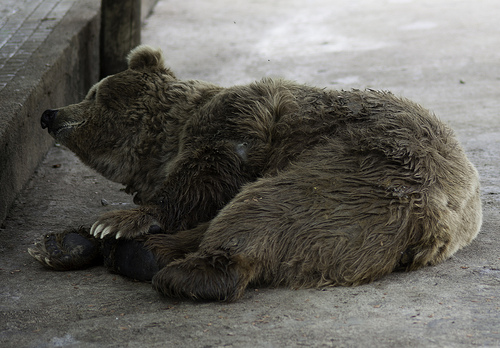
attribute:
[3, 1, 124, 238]
floor — raised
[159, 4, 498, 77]
ground — clean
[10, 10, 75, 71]
floor — bricked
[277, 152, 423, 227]
fur — brown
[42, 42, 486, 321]
fur — brown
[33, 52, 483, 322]
bear — on bear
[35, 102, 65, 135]
nose — black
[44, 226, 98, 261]
paw — black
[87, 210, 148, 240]
paw — white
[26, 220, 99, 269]
paw — white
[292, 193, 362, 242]
fur — rugged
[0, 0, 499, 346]
road — clean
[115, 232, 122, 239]
claw — sharp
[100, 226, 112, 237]
claw — sharp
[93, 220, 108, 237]
claw — sharp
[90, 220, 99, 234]
claw — sharp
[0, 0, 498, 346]
ground — clean, gray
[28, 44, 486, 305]
bear — big, brown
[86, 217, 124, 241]
claws — on bear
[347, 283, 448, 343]
ground — grey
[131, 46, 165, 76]
ear — small